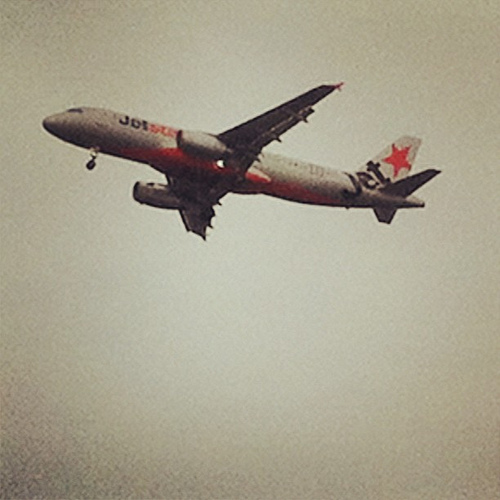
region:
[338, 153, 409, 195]
Jet written on a plane.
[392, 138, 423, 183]
A star on the plane.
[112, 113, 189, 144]
Name of the airline on the plane.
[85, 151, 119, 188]
The wheel is down.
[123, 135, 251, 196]
The bottom of the plane is red.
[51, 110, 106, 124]
Cockpit where the pilot is.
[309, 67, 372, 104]
Red light on the tip of the wing.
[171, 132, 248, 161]
Engine of the plane.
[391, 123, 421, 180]
Back wing of the plane.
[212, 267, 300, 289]
The sky is grey.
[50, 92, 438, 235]
One plane is seen.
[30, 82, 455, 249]
Plane is flying in the sky.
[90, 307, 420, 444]
Sky is white color.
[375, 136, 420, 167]
Star symbol is drawn.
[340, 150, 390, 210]
Jet word is written in plane.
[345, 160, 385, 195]
Letters are in black color.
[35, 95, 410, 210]
Plane is mainly white color.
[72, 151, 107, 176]
Landing gear is seen.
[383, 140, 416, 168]
Star is red color.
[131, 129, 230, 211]
two turbofan engine is seen.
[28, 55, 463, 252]
The plane flies in the air.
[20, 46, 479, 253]
The plane is ascending.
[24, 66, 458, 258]
The plane is tan and red.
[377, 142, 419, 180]
The plane's tail has a star graphic.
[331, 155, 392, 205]
The word jet is on the plane's tail.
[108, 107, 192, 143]
The brand name is on the plane's side.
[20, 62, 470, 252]
The plane is a commercial jet.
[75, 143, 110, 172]
The plane's landing gear is visible.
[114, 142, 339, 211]
The plane's underside is red.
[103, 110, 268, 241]
The plane has two engines.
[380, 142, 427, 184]
a red star emblem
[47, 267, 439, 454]
a blurry grey cloud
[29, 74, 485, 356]
a white commercial airliner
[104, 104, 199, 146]
the jet name brand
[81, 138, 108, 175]
plane's front landing gear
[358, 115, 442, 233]
the tail of a plane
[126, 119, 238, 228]
two large plane engines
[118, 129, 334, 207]
orange under side of a plane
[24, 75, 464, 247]
a white and orange plane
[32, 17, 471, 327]
flight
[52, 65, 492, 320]
There is a plane in the photo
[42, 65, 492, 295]
The plane is in the sky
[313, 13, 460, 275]
There is a red star on the plane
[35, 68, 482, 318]
The plane is mostly white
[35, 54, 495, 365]
The photo is not clear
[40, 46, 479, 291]
The plane has the word Jet on it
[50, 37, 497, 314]
The sky is gray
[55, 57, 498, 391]
There are no clouds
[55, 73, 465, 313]
Underneath the plane is the color red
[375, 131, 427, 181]
red star on tail wing of plane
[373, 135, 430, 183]
red star on tail wing of plane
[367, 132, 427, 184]
red star on tail wing of plane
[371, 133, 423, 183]
red star on tail wing of plane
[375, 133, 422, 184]
red star on tail wing of plane